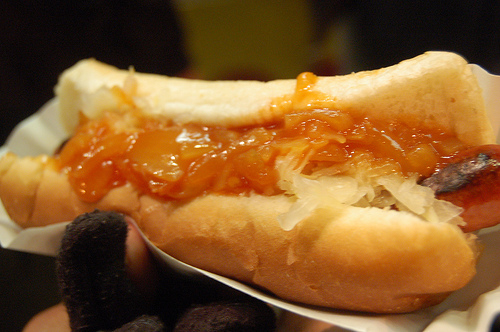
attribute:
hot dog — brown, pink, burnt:
[13, 44, 500, 273]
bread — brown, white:
[68, 60, 295, 120]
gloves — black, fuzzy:
[65, 225, 149, 318]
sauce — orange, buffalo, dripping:
[78, 114, 239, 186]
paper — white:
[0, 206, 65, 255]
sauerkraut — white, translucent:
[280, 143, 389, 203]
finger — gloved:
[68, 214, 168, 295]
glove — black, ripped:
[70, 218, 124, 297]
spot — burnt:
[431, 151, 491, 192]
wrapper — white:
[3, 111, 205, 317]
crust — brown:
[173, 232, 262, 278]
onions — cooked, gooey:
[107, 88, 140, 145]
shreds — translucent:
[372, 178, 451, 213]